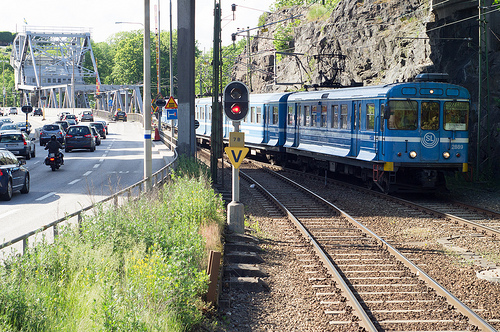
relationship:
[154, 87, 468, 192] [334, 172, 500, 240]
train on tracks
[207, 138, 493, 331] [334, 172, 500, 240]
gravel on tracks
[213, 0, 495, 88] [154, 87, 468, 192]
power cables above train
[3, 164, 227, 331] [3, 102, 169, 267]
weeds beside road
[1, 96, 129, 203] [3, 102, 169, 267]
cars on road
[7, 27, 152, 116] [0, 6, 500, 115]
bridge in background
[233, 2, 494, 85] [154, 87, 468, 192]
rock face beside train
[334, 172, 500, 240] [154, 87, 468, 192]
tracks are holding train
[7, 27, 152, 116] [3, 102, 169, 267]
bridge on road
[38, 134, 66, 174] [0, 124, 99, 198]
motorcycle between cars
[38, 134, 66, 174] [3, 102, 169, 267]
motorcycle on road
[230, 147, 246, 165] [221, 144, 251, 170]
v on sign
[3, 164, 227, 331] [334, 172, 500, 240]
weeds beside tracks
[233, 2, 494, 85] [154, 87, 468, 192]
rock face to right of train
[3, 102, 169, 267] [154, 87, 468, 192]
road to left of train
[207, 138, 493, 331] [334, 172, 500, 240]
gravel in amongst tracks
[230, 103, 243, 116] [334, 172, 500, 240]
light beside tracks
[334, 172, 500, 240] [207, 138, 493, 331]
tracks on gravel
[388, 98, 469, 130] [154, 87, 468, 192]
windshield on train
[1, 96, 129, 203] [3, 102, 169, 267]
cars on a road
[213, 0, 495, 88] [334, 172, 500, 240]
power cables above tracks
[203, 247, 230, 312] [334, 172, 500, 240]
post beside tracks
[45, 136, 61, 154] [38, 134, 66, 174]
man riding motorcycle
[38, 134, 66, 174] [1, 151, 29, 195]
motorcycle in front of car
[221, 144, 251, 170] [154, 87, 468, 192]
sign for train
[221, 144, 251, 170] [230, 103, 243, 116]
sign below light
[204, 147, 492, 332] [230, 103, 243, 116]
tracks next to light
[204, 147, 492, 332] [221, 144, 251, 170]
tracks next to sign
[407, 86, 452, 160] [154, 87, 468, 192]
lights on train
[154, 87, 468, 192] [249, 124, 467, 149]
train has a stripe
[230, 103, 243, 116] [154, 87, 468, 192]
light for train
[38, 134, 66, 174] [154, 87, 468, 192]
motorcycle riding towards train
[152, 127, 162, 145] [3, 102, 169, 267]
caution cone on side of road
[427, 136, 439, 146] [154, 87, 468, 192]
sl on train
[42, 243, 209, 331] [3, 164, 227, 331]
flowers in weeds